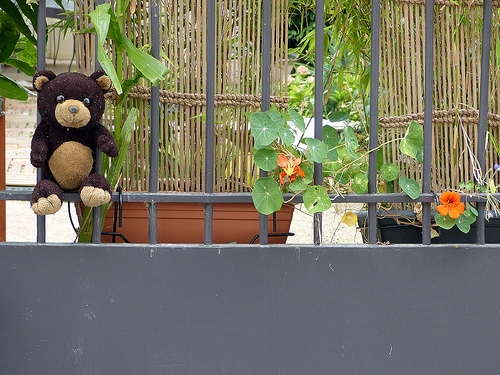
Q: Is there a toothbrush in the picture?
A: No, there are no toothbrushes.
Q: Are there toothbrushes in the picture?
A: No, there are no toothbrushes.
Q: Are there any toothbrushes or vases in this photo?
A: No, there are no toothbrushes or vases.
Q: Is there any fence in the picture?
A: Yes, there is a fence.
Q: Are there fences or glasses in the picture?
A: Yes, there is a fence.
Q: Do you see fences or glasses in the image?
A: Yes, there is a fence.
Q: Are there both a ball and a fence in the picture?
A: No, there is a fence but no balls.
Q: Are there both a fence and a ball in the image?
A: No, there is a fence but no balls.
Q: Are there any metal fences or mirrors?
A: Yes, there is a metal fence.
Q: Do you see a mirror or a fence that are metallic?
A: Yes, the fence is metallic.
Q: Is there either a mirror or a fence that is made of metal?
A: Yes, the fence is made of metal.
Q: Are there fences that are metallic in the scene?
A: Yes, there is a metal fence.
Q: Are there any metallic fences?
A: Yes, there is a metal fence.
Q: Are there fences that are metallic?
A: Yes, there is a fence that is metallic.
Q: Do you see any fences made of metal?
A: Yes, there is a fence that is made of metal.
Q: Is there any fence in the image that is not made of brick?
A: Yes, there is a fence that is made of metal.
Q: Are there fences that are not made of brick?
A: Yes, there is a fence that is made of metal.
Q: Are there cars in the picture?
A: No, there are no cars.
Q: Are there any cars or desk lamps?
A: No, there are no cars or desk lamps.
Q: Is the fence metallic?
A: Yes, the fence is metallic.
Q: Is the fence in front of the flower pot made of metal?
A: Yes, the fence is made of metal.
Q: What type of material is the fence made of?
A: The fence is made of metal.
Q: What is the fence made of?
A: The fence is made of metal.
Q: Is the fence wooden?
A: No, the fence is metallic.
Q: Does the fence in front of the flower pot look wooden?
A: No, the fence is metallic.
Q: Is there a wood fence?
A: No, there is a fence but it is made of metal.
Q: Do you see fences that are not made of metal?
A: No, there is a fence but it is made of metal.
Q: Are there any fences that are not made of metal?
A: No, there is a fence but it is made of metal.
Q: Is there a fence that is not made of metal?
A: No, there is a fence but it is made of metal.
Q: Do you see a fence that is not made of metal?
A: No, there is a fence but it is made of metal.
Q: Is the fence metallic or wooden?
A: The fence is metallic.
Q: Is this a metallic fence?
A: Yes, this is a metallic fence.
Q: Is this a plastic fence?
A: No, this is a metallic fence.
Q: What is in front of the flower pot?
A: The fence is in front of the flower pot.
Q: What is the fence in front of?
A: The fence is in front of the flower pot.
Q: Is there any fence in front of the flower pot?
A: Yes, there is a fence in front of the flower pot.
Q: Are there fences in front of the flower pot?
A: Yes, there is a fence in front of the flower pot.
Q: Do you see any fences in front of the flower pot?
A: Yes, there is a fence in front of the flower pot.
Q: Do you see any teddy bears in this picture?
A: Yes, there is a teddy bear.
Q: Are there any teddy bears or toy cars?
A: Yes, there is a teddy bear.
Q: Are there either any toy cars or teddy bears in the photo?
A: Yes, there is a teddy bear.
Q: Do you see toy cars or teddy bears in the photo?
A: Yes, there is a teddy bear.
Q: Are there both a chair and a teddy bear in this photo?
A: No, there is a teddy bear but no chairs.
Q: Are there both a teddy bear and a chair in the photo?
A: No, there is a teddy bear but no chairs.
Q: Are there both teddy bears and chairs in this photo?
A: No, there is a teddy bear but no chairs.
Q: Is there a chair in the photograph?
A: No, there are no chairs.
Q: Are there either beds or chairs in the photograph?
A: No, there are no chairs or beds.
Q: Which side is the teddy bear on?
A: The teddy bear is on the left of the image.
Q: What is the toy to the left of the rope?
A: The toy is a teddy bear.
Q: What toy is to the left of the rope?
A: The toy is a teddy bear.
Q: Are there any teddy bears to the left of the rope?
A: Yes, there is a teddy bear to the left of the rope.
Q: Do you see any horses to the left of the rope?
A: No, there is a teddy bear to the left of the rope.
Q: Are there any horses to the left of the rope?
A: No, there is a teddy bear to the left of the rope.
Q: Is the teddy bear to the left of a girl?
A: No, the teddy bear is to the left of the rope.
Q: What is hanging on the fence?
A: The teddy bear is hanging on the fence.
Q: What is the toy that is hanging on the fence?
A: The toy is a teddy bear.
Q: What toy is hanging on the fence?
A: The toy is a teddy bear.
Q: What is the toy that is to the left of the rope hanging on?
A: The teddy bear is hanging on the fence.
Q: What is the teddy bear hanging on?
A: The teddy bear is hanging on the fence.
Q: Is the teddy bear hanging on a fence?
A: Yes, the teddy bear is hanging on a fence.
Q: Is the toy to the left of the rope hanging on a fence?
A: Yes, the teddy bear is hanging on a fence.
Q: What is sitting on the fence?
A: The teddy bear is sitting on the fence.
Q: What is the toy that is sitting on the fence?
A: The toy is a teddy bear.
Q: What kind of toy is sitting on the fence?
A: The toy is a teddy bear.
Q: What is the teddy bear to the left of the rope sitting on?
A: The teddy bear is sitting on the fence.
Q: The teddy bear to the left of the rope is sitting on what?
A: The teddy bear is sitting on the fence.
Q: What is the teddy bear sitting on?
A: The teddy bear is sitting on the fence.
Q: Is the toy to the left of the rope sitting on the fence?
A: Yes, the teddy bear is sitting on the fence.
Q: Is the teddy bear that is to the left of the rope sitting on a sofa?
A: No, the teddy bear is sitting on the fence.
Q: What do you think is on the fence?
A: The teddy bear is on the fence.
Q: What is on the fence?
A: The teddy bear is on the fence.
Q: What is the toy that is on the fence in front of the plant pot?
A: The toy is a teddy bear.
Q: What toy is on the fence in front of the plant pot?
A: The toy is a teddy bear.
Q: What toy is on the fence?
A: The toy is a teddy bear.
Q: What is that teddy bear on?
A: The teddy bear is on the fence.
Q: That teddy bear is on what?
A: The teddy bear is on the fence.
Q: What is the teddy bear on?
A: The teddy bear is on the fence.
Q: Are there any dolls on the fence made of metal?
A: No, there is a teddy bear on the fence.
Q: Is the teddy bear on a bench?
A: No, the teddy bear is on the fence.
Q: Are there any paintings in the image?
A: No, there are no paintings.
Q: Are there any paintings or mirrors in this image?
A: No, there are no paintings or mirrors.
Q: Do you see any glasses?
A: No, there are no glasses.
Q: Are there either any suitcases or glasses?
A: No, there are no glasses or suitcases.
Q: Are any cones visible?
A: No, there are no cones.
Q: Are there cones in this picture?
A: No, there are no cones.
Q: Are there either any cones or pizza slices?
A: No, there are no cones or pizza slices.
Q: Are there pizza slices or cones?
A: No, there are no cones or pizza slices.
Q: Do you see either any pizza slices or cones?
A: No, there are no cones or pizza slices.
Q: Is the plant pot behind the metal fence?
A: Yes, the plant pot is behind the fence.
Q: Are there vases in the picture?
A: No, there are no vases.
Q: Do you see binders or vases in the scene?
A: No, there are no vases or binders.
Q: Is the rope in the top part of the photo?
A: Yes, the rope is in the top of the image.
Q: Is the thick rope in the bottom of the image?
A: No, the rope is in the top of the image.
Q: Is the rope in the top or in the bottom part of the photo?
A: The rope is in the top of the image.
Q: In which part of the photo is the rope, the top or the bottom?
A: The rope is in the top of the image.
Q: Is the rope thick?
A: Yes, the rope is thick.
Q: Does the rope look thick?
A: Yes, the rope is thick.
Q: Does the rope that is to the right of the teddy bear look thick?
A: Yes, the rope is thick.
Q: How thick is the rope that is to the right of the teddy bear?
A: The rope is thick.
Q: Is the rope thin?
A: No, the rope is thick.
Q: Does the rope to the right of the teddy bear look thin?
A: No, the rope is thick.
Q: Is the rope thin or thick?
A: The rope is thick.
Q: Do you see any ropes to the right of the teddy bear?
A: Yes, there is a rope to the right of the teddy bear.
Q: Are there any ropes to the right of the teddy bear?
A: Yes, there is a rope to the right of the teddy bear.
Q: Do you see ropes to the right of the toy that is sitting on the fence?
A: Yes, there is a rope to the right of the teddy bear.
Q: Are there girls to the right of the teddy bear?
A: No, there is a rope to the right of the teddy bear.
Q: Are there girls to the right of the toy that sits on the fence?
A: No, there is a rope to the right of the teddy bear.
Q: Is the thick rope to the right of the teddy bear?
A: Yes, the rope is to the right of the teddy bear.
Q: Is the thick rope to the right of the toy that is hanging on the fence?
A: Yes, the rope is to the right of the teddy bear.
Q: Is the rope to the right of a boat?
A: No, the rope is to the right of the teddy bear.